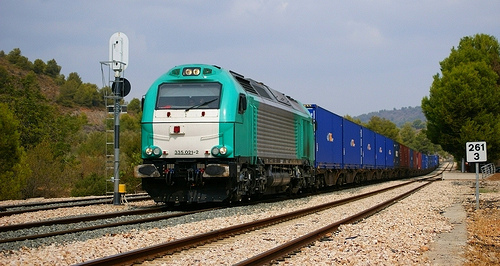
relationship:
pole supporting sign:
[469, 158, 489, 218] [463, 138, 483, 161]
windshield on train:
[157, 81, 226, 109] [136, 61, 444, 208]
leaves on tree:
[43, 117, 68, 142] [16, 136, 63, 203]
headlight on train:
[144, 145, 161, 155] [136, 61, 444, 208]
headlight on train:
[210, 143, 227, 157] [136, 61, 444, 208]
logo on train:
[323, 124, 340, 143] [135, 52, 302, 212]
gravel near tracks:
[0, 179, 457, 263] [29, 186, 495, 264]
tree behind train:
[420, 33, 499, 173] [136, 61, 444, 208]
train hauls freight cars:
[136, 61, 444, 208] [309, 98, 450, 186]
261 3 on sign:
[465, 140, 488, 160] [454, 130, 488, 182]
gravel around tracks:
[1, 156, 498, 262] [1, 157, 453, 264]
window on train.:
[154, 79, 223, 112] [58, 47, 450, 224]